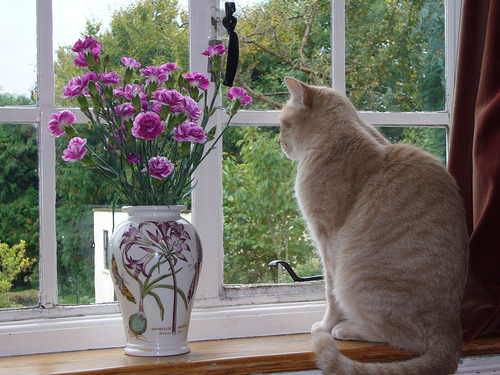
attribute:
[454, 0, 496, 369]
curtain — brown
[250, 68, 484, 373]
cat — beige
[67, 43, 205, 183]
flowers — purple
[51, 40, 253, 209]
flowers — purple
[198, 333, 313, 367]
window sill — brown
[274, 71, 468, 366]
cat — brown, striped